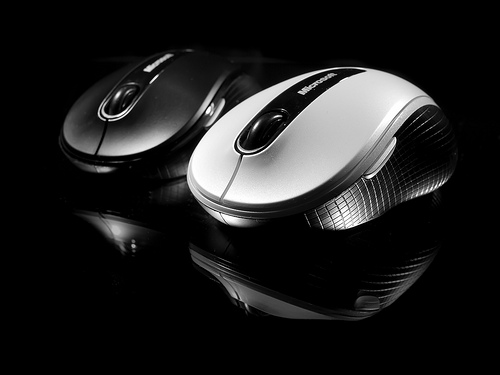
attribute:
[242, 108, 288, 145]
roller — black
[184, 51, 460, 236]
mouse — black, white, optical, silver, textured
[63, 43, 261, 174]
mouse — optical, black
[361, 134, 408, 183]
tab — small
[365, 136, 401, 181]
button — black, white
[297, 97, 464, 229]
pattern — crisscross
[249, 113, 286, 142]
wheel — black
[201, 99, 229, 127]
button — black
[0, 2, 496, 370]
background — black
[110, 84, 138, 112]
roller — black